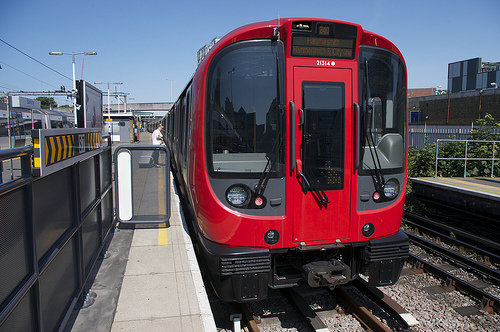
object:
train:
[168, 14, 404, 287]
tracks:
[222, 275, 425, 328]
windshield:
[208, 32, 287, 170]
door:
[294, 68, 354, 246]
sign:
[26, 122, 117, 169]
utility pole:
[64, 40, 85, 146]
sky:
[110, 6, 185, 77]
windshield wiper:
[361, 97, 385, 204]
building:
[412, 46, 496, 139]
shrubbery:
[412, 117, 499, 168]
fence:
[407, 118, 496, 181]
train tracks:
[402, 209, 497, 329]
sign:
[28, 127, 104, 176]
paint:
[155, 150, 170, 245]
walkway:
[137, 84, 171, 330]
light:
[228, 183, 254, 209]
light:
[382, 178, 401, 200]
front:
[192, 17, 410, 308]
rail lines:
[414, 209, 496, 330]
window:
[208, 45, 285, 178]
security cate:
[110, 131, 175, 230]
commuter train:
[160, 14, 414, 294]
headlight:
[227, 181, 251, 209]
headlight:
[380, 178, 415, 199]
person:
[148, 123, 166, 158]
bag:
[137, 148, 155, 168]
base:
[390, 258, 498, 330]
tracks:
[393, 209, 498, 329]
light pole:
[48, 50, 108, 129]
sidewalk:
[75, 127, 215, 329]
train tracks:
[228, 280, 418, 330]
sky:
[1, 4, 497, 102]